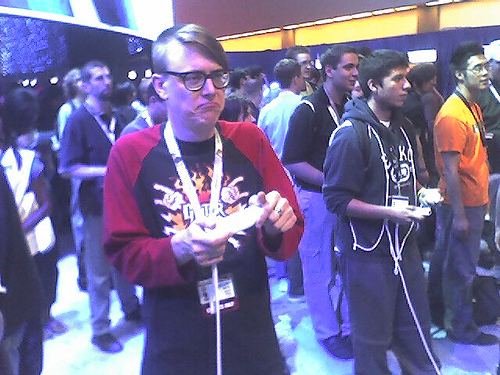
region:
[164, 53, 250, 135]
the man wearing eyeglasses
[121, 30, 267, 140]
the man wearing eyeglasses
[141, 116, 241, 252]
man wearing a lanyard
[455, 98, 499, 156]
man wearing a lanyard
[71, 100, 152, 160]
man wearing a lanyard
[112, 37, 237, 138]
a man wearing glasses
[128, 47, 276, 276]
a man holding a game controller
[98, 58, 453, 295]
two men holding game controllers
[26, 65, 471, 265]
several people standing together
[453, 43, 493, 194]
a man with a camera around his neck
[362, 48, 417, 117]
a man with black hair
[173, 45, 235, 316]
a man with a tag around his neck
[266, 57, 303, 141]
a man wearing a white shirt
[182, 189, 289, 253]
a white game controller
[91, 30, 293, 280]
a man wearing a black and red shirt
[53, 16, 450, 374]
group of wii players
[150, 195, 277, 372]
remote wii controller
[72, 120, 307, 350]
man wears Guitar Hero t-shirt with red sleeves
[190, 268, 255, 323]
a name tag on neck lanyard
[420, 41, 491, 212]
man with bright orange shirt watches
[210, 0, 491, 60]
a yellow light across wall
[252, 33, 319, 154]
back of a white dress shirt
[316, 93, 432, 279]
a dark hoodie with white print on front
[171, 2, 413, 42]
portion of a brown wall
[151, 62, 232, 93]
black rimmed eyeglasses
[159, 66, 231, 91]
the glasses on the man's face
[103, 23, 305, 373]
tthe man standing holding a wii controller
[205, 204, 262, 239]
the wii controller in the man's hand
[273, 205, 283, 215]
the ring on the man's finger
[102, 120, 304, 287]
the red long sleeves on the man's shirt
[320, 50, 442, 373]
the standing man dressed all in dark clothing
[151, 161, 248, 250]
the design on the front of the man's shirt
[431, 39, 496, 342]
the standing man wearing an orange shirt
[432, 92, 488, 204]
the orange short sleeved shirt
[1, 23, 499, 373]
the large crowd of people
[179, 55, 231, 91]
Eyeglasses in the photo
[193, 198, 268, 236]
Joysticks in the photo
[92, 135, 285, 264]
Red and black t-shirt.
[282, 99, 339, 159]
Black t-shirt in the photo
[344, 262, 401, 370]
Black pants in the photo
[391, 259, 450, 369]
A cable in the photo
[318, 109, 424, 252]
A man with a black hoodie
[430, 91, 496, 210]
An orange t-shirt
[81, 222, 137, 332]
Blue trousers in the photo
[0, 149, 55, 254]
White top in the photo